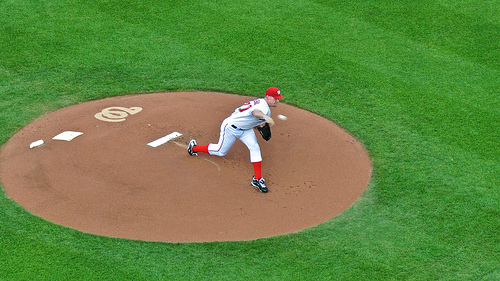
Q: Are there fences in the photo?
A: No, there are no fences.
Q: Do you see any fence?
A: No, there are no fences.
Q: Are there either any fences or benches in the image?
A: No, there are no fences or benches.